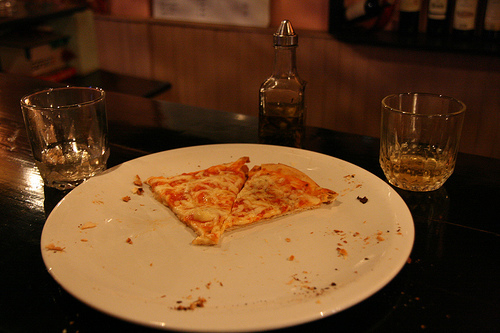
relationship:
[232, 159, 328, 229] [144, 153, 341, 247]
slice of pizza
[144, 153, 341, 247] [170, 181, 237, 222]
pizza topped with cheese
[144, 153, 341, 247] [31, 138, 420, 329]
pizza on plate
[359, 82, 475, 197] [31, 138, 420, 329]
glass by plate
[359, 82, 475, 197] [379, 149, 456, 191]
glass full of liquid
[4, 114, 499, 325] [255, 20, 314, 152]
table top has olive oil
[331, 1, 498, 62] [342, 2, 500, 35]
rack has wines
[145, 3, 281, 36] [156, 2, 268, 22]
board has menu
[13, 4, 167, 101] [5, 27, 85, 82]
shelves hold items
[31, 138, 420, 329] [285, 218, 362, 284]
plate has crumbs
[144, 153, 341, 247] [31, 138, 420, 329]
pizza on a plate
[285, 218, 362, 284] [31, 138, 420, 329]
crumbs are on a plate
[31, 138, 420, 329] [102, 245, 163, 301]
plate colored white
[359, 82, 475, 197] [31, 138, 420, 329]
glass right of plate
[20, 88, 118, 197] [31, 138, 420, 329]
glass left of plate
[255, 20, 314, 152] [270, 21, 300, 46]
bottle has spout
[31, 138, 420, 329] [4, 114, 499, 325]
plate on table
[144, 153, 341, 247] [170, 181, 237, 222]
pizza has cheese topping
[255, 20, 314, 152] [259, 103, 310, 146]
dispenser has oil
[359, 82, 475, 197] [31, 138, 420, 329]
glass near plate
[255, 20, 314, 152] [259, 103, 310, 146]
bottle has olive oil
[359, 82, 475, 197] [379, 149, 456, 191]
glass filled with liquid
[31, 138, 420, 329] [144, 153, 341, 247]
plate holding pizza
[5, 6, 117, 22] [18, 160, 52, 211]
lights have glare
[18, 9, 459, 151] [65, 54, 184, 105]
background has bench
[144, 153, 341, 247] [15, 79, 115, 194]
slices and glass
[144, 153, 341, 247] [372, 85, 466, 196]
slices and glass